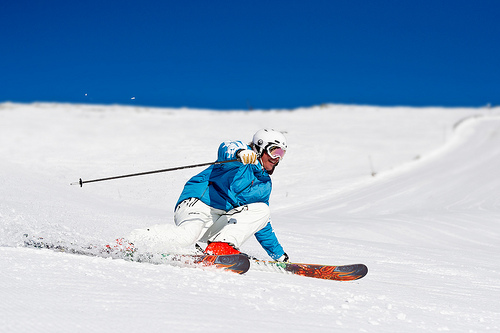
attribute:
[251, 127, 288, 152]
helmet — white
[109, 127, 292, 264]
person — skiing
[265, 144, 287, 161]
goggles — pink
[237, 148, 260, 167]
glove — white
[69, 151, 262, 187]
ski pole — black, midair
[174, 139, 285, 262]
jacket — blue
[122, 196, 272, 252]
pants — white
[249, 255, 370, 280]
ski — blue, sideways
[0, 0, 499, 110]
sky — blue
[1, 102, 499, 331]
snow — slope, white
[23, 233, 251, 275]
ski — orange